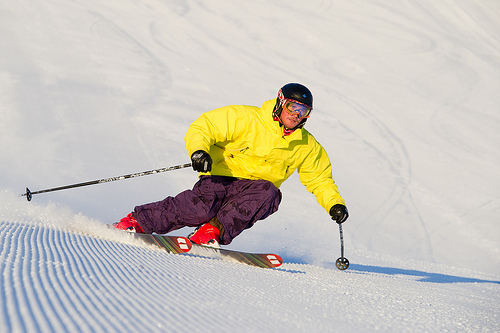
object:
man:
[17, 82, 350, 270]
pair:
[11, 158, 354, 275]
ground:
[0, 0, 500, 328]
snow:
[6, 0, 498, 325]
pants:
[133, 173, 282, 247]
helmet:
[272, 83, 313, 127]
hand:
[329, 206, 348, 224]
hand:
[191, 149, 213, 173]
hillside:
[0, 1, 499, 333]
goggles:
[278, 98, 313, 119]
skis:
[109, 232, 282, 269]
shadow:
[273, 252, 500, 289]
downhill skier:
[19, 83, 348, 271]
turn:
[108, 231, 292, 269]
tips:
[264, 254, 283, 267]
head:
[273, 83, 312, 131]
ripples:
[0, 216, 500, 328]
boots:
[186, 223, 224, 249]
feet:
[186, 221, 224, 249]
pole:
[334, 221, 346, 270]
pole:
[20, 161, 195, 202]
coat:
[185, 99, 358, 212]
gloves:
[325, 204, 349, 224]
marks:
[0, 211, 500, 332]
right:
[255, 0, 495, 332]